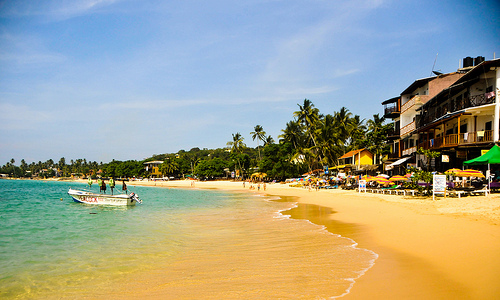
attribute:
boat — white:
[67, 187, 141, 208]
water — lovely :
[2, 179, 378, 299]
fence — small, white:
[356, 180, 422, 197]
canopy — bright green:
[461, 141, 499, 166]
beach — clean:
[224, 187, 469, 290]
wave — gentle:
[245, 183, 379, 298]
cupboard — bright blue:
[383, 25, 441, 61]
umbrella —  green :
[464, 143, 499, 178]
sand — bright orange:
[3, 176, 499, 298]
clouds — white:
[67, 53, 229, 138]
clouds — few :
[0, 78, 338, 133]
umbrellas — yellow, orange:
[353, 172, 408, 184]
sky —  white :
[128, 5, 264, 57]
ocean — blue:
[8, 181, 63, 241]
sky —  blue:
[49, 17, 360, 60]